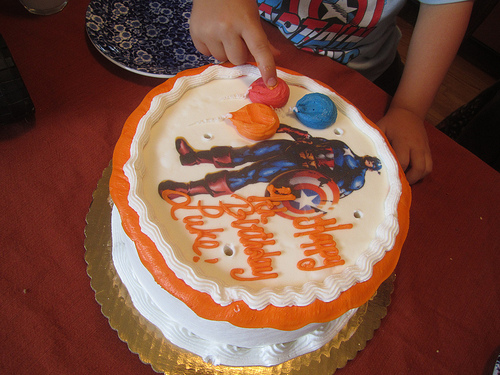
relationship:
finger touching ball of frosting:
[244, 30, 279, 86] [248, 76, 292, 108]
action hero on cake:
[157, 127, 381, 220] [108, 63, 414, 364]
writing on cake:
[162, 188, 353, 280] [108, 63, 414, 364]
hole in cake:
[225, 247, 234, 260] [108, 63, 414, 364]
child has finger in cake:
[189, 2, 475, 184] [108, 63, 414, 364]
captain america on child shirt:
[268, 0, 383, 64] [256, 1, 402, 82]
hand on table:
[378, 108, 436, 183] [3, 0, 499, 374]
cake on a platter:
[108, 63, 414, 364] [82, 156, 395, 371]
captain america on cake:
[157, 127, 381, 220] [108, 63, 414, 364]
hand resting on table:
[378, 108, 436, 183] [3, 0, 499, 374]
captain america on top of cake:
[157, 127, 381, 220] [108, 63, 414, 364]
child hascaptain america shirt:
[189, 2, 475, 184] [256, 1, 402, 82]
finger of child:
[244, 30, 279, 86] [189, 2, 475, 184]